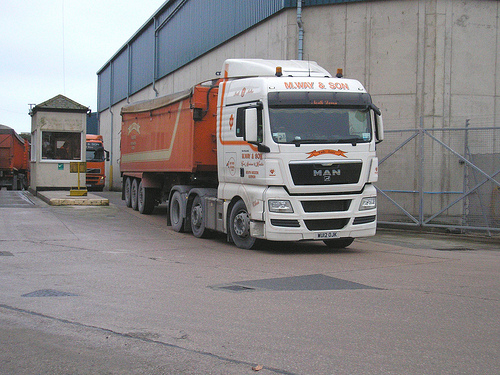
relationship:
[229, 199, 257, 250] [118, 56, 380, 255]
front tire are on truck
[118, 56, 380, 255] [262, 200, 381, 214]
truck has headlights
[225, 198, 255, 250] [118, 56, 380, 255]
front tire of truck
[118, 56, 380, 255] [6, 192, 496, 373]
truck on pavement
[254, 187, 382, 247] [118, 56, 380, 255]
grill of truck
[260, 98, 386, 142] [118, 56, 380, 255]
windshield of truck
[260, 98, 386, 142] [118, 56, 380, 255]
mirrors are on truck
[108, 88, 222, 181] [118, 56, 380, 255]
truckload on truck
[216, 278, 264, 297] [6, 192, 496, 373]
vent in pavement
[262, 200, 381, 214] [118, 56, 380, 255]
headlights of truck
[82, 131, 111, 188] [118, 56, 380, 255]
orange truck behind truck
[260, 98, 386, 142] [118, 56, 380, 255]
windshield on truck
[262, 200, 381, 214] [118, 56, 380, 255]
headlights are on truck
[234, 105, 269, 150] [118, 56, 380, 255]
side mirror on truck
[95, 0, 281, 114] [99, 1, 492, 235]
blue siding on building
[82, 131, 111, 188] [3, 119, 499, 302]
orange truck in lot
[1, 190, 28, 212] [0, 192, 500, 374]
track on pavement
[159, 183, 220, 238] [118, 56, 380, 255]
center wheels of truck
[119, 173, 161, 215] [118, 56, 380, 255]
back wheels of truck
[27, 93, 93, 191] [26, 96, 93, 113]
shelter has black roof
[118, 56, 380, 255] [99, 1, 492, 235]
truck in front of building